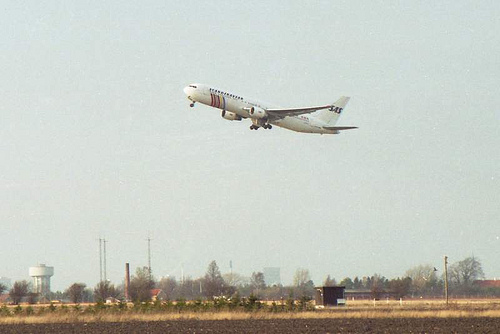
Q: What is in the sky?
A: A plane.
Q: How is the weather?
A: Cleat.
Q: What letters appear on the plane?
A: SAS.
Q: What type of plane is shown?
A: Commercial airliner.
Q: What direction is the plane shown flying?
A: Left.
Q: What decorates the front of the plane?
A: Stripes.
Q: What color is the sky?
A: Gray.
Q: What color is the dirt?
A: Brown.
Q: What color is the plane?
A: White.